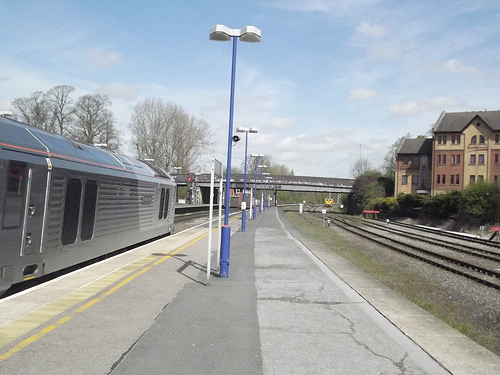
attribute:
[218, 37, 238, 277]
pole — blue, light blue, metal, skinny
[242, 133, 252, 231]
pole — blue, metal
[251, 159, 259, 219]
pole — blue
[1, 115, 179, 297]
train — silver, gray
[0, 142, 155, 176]
stripe — red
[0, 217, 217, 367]
line — yellow, faded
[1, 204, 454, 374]
platform — concrete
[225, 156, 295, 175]
trees — bare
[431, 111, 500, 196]
building — brown, tan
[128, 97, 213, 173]
trees — bare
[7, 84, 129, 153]
trees — bare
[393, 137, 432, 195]
building — brown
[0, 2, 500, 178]
sky — blue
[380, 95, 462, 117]
cloud — white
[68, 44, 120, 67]
cloud — white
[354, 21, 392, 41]
cloud — white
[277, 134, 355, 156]
cloud — white